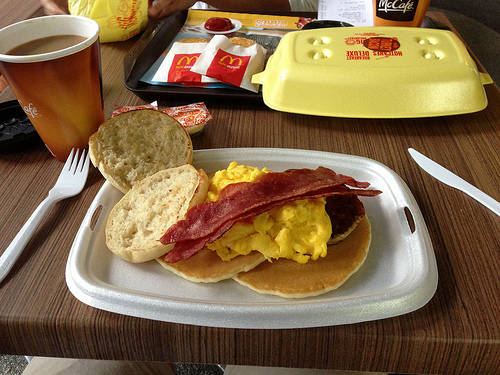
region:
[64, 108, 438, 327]
McDonald's breakfast meal on tray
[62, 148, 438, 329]
white tray is styrofoam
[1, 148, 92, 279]
white fork is plastic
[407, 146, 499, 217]
white knife is plastic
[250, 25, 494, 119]
yellow styrofoam meal lid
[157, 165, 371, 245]
top slice of bacon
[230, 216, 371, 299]
bottom pancake on tray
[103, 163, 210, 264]
bottom half of English muffin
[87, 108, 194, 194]
top half of English muffin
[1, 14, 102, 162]
paper cup with coffee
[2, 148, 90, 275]
white plastic fork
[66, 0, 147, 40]
yellow wrapper with red writing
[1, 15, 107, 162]
coffee cup with coffee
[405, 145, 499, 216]
white plastic butter knife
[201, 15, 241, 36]
plastic container filled with ketchup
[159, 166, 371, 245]
slice of bacon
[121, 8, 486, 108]
brown McDonald's food tray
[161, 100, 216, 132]
closed butter packet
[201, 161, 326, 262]
yellow scrambled eggs on top of pancakes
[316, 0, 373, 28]
white receipt with blue lettering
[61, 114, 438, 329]
Breakfast tray of food from McDonalds.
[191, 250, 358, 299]
Edge of two hotcakes.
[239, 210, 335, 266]
Edge of delicious looking scramble eggs.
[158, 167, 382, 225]
Two pieces of crisp bacon.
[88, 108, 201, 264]
Lightly toasted english muffin.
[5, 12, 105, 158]
Cup of coffee sitting on table.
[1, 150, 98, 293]
Plastic fork lying on table.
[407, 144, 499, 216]
Plastic knife lying on table.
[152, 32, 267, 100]
Two hash browns lying on tray.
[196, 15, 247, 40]
Small tub of ketchup on tray.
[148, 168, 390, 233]
strips of bacon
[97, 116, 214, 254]
cut open biscuit on plate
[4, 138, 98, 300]
white plastic fork on table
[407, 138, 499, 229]
white plastic knife on table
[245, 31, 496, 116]
yellow styrofoam container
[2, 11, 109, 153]
cardboard cup of coffee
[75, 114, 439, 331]
stryofoam plate with breakfast foods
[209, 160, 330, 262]
yellow scrambled eggs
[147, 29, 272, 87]
hash browns in mcdonald's wrappers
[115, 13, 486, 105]
brown plastic tray on table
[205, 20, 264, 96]
McDonald has brown in wrapper.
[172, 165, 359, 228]
Bacon on top of eggs.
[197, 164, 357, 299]
Scrambled eggs on top of pancakes.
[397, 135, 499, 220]
White plastic knife on table.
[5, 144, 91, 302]
White plastic fork on table.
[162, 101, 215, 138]
Butter packet on table.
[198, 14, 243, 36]
Ketchup in container on tray.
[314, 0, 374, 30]
Receipt for food on tray.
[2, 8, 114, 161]
Cup of coffee on table.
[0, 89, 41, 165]
Black coffee lid on table.